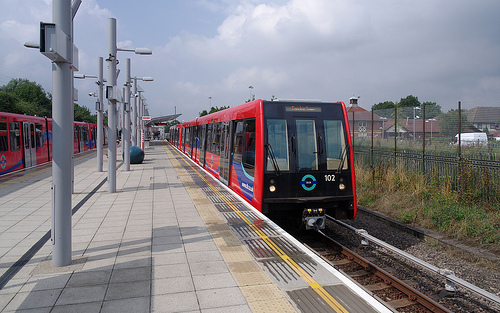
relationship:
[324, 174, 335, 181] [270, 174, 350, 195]
102 on black background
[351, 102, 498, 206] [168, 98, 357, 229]
fence on side of trai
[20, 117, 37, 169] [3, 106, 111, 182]
door on passenger train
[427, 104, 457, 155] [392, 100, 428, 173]
wire fencing on poles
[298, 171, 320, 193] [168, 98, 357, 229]
logo on trai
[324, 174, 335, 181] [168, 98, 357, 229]
102 on trai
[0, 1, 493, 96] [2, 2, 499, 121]
cloud in sky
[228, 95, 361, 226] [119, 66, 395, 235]
first car on train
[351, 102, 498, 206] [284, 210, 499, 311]
fence by tracks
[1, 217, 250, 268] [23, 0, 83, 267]
shadow of utility pole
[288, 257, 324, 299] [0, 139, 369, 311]
line on platform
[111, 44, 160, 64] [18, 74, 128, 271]
streetlight on pole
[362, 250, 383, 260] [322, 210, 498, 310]
dirt between track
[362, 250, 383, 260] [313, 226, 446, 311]
dirt between track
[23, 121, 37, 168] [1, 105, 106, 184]
door on train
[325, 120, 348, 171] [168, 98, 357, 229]
front window on trai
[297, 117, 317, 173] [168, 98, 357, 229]
front window on trai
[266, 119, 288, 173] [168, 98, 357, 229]
front window on trai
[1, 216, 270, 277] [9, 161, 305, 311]
shadow on ground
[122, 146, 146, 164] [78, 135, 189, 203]
ball on ground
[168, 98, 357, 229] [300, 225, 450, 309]
trai on top of track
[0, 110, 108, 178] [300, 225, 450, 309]
passenger train on top of track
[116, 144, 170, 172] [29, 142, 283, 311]
ball on train platform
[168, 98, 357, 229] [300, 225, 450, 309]
trai on track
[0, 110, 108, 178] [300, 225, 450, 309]
passenger train on track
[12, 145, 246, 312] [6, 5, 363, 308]
platform on train area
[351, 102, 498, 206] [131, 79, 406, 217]
fence near train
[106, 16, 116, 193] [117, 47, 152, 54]
pole with street light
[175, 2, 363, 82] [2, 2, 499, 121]
cloud in sky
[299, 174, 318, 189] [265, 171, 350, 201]
circle on background